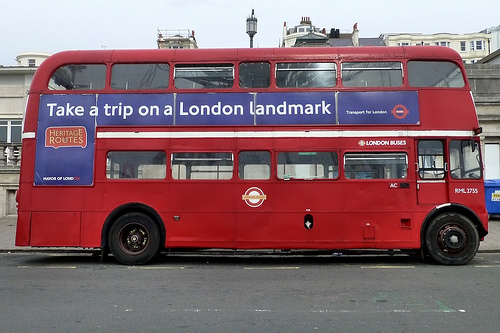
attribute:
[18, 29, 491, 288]
bus — double decker.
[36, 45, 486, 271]
bus — two tiered, double decker.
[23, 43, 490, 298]
bus — double-decker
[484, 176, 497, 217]
garbage bin — blue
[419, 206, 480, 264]
wheel — black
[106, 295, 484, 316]
markings — white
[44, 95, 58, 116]
letter — white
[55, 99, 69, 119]
letter — white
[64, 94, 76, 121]
letter — white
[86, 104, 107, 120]
letter — white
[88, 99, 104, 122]
letter — white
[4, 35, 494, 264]
bus — double decker.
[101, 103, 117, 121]
letter — white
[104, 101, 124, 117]
letter — white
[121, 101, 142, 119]
letter — white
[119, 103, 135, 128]
letter — white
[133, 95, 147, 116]
letter — white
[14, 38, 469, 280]
bus — double decker.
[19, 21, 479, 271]
bus — double decker.